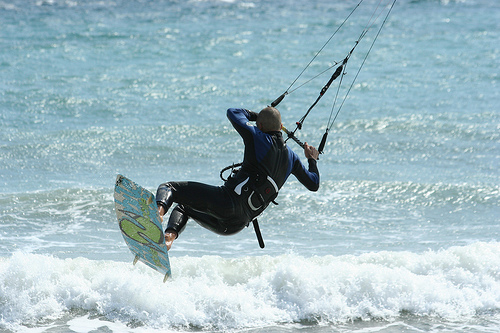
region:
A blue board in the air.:
[107, 180, 173, 292]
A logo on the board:
[120, 204, 165, 259]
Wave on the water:
[195, 224, 497, 331]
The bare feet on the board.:
[147, 202, 172, 254]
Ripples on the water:
[404, 19, 462, 92]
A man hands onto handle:
[147, 88, 349, 239]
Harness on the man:
[204, 167, 292, 224]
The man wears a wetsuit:
[144, 86, 333, 251]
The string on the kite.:
[282, 4, 390, 116]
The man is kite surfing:
[105, 20, 397, 293]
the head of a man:
[250, 99, 288, 135]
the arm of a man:
[222, 103, 260, 138]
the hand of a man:
[302, 138, 324, 160]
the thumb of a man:
[301, 140, 311, 156]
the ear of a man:
[278, 119, 286, 132]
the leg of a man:
[149, 172, 237, 212]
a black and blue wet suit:
[151, 105, 321, 239]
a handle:
[257, 101, 326, 166]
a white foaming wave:
[1, 240, 498, 331]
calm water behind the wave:
[1, 0, 498, 181]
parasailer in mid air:
[155, 104, 324, 279]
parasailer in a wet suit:
[155, 102, 323, 247]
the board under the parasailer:
[113, 171, 173, 288]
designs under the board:
[114, 180, 163, 270]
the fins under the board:
[126, 255, 174, 283]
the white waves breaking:
[3, 258, 430, 328]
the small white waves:
[20, 269, 409, 326]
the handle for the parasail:
[256, 102, 328, 162]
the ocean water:
[23, 20, 211, 150]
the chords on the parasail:
[280, 2, 432, 122]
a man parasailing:
[42, 9, 499, 311]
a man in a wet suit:
[76, 87, 394, 331]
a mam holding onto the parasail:
[127, 65, 398, 285]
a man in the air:
[67, 49, 470, 331]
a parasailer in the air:
[65, 70, 470, 330]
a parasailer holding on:
[94, 67, 474, 328]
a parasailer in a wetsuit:
[69, 48, 471, 257]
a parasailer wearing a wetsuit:
[118, 66, 373, 273]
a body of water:
[314, 125, 499, 297]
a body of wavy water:
[336, 130, 482, 281]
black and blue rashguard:
[166, 107, 296, 249]